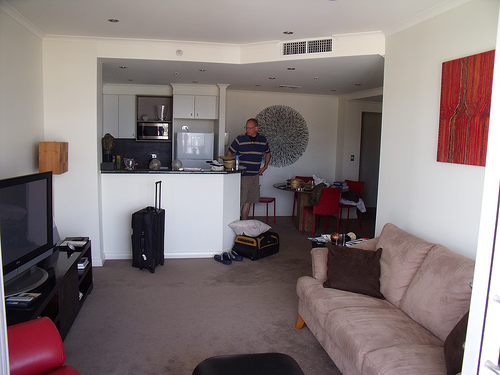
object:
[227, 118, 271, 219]
man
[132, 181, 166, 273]
suitcase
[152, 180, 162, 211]
handle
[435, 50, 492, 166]
artwork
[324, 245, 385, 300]
pillow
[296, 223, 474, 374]
couch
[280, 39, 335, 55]
vent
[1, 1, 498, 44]
ceiling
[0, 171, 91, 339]
entertainment center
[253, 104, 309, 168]
decoration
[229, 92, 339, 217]
wall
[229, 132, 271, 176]
shirt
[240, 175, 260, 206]
shorts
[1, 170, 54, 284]
television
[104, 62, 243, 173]
kitchen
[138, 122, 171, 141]
microwave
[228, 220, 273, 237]
pillow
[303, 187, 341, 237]
chair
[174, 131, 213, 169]
refrigerator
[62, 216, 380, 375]
floor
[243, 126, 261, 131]
glasses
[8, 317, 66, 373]
arm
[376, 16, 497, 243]
wall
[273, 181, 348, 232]
table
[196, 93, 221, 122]
cabinet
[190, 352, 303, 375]
ottoman